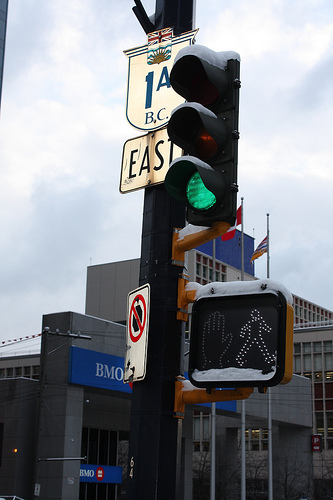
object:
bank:
[0, 310, 315, 500]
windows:
[314, 400, 323, 412]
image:
[235, 309, 273, 367]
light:
[186, 171, 216, 210]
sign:
[164, 43, 243, 257]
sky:
[0, 0, 333, 359]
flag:
[147, 27, 173, 47]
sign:
[124, 282, 151, 383]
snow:
[185, 279, 293, 305]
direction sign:
[119, 128, 182, 194]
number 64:
[130, 457, 135, 479]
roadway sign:
[123, 27, 200, 132]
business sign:
[68, 346, 237, 414]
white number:
[127, 455, 137, 480]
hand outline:
[202, 312, 233, 368]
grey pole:
[210, 403, 215, 499]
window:
[314, 371, 322, 381]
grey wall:
[37, 359, 61, 487]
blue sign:
[79, 464, 122, 483]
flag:
[221, 205, 242, 242]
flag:
[250, 236, 268, 265]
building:
[85, 249, 333, 451]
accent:
[195, 228, 255, 277]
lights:
[246, 429, 267, 438]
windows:
[250, 440, 259, 450]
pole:
[267, 213, 273, 470]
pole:
[241, 196, 246, 500]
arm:
[172, 224, 231, 262]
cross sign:
[188, 279, 294, 395]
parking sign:
[312, 435, 321, 451]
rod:
[43, 330, 92, 341]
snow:
[75, 312, 126, 328]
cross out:
[129, 294, 146, 343]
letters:
[95, 363, 123, 381]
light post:
[125, 0, 194, 500]